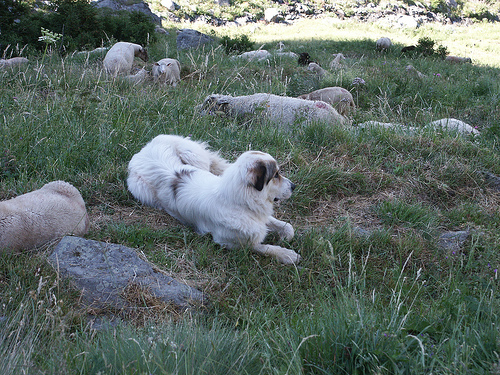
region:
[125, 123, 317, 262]
DOG LAYING IN THE GRASS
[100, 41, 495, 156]
SHEEP LAYING IN THE FIELDS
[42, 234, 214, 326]
ROCK IN THE FIELD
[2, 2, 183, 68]
GREEN BUSHES IN THE TOP LEFT OF PICTURE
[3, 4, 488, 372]
MOST OF THE GRASS IS GREEN IN THE FIELD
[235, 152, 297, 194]
DOG HAS BROWN EARS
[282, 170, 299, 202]
BLACK NOSE ON THE DOG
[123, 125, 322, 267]
DOG IS TAN, BLACK AND WHITE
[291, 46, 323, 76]
ONE BLACK SHEEP IN THE FIELD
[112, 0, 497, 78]
TOP RIGHT OF PICTURE IS BRIGHT FROM THE SUN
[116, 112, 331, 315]
a mostly white dog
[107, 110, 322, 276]
dog laying down in grass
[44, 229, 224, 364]
a rock among the grass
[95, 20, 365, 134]
a group of sheep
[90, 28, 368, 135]
sheep resting among grass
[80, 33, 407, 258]
dog relaxing among sheep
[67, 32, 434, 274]
dog watching over sheep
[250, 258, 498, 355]
long blades of grass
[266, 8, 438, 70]
sun shining on grass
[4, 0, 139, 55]
group of green bushes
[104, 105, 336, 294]
a working sheep dog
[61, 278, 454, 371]
some tall patches of grass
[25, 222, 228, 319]
a large flat rock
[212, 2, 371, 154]
a few sheep laying down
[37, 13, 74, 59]
a tall flowering plant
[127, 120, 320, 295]
a brown and white dog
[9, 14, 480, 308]
dog watching a herd of sheep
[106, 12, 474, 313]
a shady patch of grass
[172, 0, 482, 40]
a few short plants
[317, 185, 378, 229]
a dry patch of grass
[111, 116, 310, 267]
Dog is lying down.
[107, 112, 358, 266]
A dog on the grass.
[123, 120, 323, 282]
The dog is furry.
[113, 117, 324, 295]
Dog is black and white.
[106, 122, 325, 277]
The dog is alert.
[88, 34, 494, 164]
Sheep are wandering around.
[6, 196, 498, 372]
Rocky area in grass.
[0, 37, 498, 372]
The grass is overgrown.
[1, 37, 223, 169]
The sheep is standing.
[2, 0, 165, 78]
The tree is green.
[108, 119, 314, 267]
the dog in the field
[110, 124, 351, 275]
the dog is white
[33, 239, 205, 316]
the rock near the dog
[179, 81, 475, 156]
the sheep in the field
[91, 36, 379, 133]
the sheep are laying down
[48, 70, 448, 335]
the field of grass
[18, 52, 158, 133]
the tall stalks of grass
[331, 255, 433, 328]
the stalks are dry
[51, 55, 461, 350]
the grass is shaded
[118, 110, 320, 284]
the dog is laying down